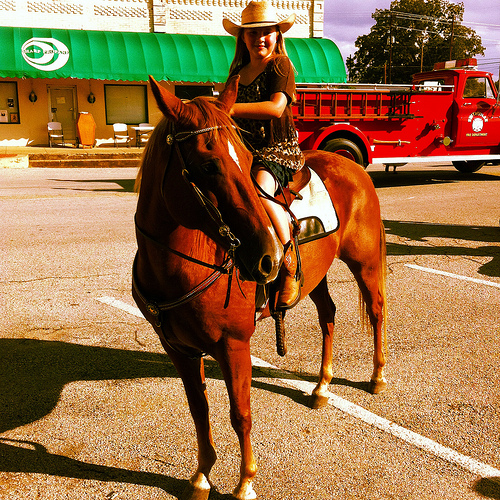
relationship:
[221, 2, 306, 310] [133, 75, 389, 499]
girl riding on horse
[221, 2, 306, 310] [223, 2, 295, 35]
girl in cowboy hat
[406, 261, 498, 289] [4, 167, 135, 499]
line on ground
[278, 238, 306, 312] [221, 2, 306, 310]
boot on girl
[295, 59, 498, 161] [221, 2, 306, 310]
firetruck behind girl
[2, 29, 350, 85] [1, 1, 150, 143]
awning on building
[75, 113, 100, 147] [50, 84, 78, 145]
coffin by door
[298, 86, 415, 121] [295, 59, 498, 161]
ladder on firetruck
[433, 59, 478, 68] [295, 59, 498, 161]
light on top of firetruck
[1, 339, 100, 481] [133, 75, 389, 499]
shadow of horse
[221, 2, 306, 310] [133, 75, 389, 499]
girl sitting on horse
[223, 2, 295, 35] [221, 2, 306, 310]
hat on head of girl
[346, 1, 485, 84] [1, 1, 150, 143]
tree behind building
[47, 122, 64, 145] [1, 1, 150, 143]
chair in front of building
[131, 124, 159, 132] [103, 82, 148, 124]
table in from of window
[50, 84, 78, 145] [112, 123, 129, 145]
door and chair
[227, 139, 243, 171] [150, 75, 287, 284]
spot on head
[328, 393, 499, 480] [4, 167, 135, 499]
line on ground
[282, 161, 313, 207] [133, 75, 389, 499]
saddle on horse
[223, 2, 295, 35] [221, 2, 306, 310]
hat on girl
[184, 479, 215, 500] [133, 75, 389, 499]
hoof on horse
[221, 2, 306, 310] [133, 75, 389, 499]
girl on back of horse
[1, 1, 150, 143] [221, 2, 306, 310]
building behind girl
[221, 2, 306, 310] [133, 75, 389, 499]
girl on horse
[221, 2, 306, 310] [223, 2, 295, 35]
girl wearing hat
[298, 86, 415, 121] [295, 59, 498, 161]
ladder hanging on firetruck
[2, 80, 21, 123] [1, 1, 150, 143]
window on building